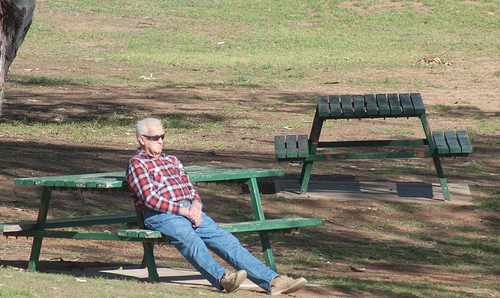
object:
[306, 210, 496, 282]
ground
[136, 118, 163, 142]
hair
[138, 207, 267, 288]
blue sky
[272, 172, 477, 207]
concerete slab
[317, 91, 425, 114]
table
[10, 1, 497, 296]
park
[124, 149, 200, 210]
plaid shirt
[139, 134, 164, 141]
sunglasses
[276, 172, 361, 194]
shadows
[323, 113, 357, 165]
wall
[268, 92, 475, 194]
picnic bench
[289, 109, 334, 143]
wall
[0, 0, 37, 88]
tree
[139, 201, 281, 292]
jeans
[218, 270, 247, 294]
shoes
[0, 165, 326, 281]
picnic beach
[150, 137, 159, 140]
eyes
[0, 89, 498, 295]
shadow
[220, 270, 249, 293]
feet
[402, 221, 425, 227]
grass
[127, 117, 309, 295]
man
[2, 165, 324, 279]
bench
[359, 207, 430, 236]
dirt